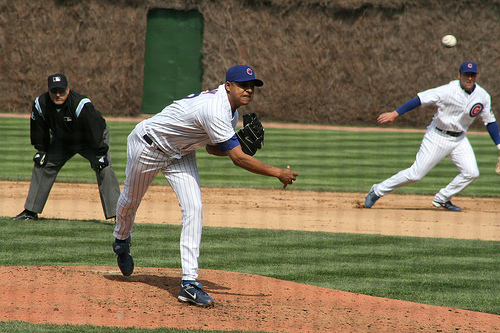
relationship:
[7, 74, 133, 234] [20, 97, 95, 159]
baseball player wearing jacket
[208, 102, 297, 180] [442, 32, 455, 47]
arm throwing ball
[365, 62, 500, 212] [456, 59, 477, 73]
baseball player wearing cap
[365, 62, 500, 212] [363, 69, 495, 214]
baseball player wearing white shirt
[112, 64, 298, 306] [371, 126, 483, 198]
baseball player wearing pants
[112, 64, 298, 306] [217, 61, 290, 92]
baseball player wearing cap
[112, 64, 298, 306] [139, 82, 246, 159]
baseball player wearing white shirt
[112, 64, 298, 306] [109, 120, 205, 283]
baseball player wearing white pants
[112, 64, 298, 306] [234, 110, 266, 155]
baseball player holding glove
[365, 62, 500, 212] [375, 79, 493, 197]
baseball player wears team uniform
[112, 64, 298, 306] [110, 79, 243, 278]
baseball player wears uniform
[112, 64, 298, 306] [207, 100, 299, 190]
baseball player with arm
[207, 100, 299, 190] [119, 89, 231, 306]
arm across body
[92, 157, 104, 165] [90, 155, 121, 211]
hands on legs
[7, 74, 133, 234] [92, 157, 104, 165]
baseball player with hands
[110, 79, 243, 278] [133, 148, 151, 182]
uniform with stripes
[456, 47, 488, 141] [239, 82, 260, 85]
cap shielding eyes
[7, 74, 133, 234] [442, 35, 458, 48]
baseball player playing ball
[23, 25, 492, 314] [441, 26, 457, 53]
people playing baseball